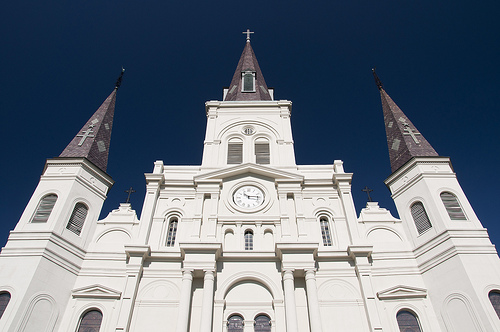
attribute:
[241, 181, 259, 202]
hands — black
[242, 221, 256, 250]
window — small, arched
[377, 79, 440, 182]
steeple — thatched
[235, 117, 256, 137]
vent — round, barred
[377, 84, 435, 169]
steeple — pointed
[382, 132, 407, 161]
diamond shape — grey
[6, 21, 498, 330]
church — stone, light colored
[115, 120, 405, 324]
building — white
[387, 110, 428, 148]
cross — light gray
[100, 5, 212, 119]
sky — blue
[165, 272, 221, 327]
pillar — white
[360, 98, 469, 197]
steeple — brownish red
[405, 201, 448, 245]
window — boarded up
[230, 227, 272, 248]
window case — arched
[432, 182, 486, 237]
window — closed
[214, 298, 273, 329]
arch — double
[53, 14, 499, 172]
sky — cloudless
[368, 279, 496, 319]
accent — triangular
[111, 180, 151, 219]
cross — metal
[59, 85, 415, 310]
church — large, white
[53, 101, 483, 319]
church — white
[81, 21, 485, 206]
spires — brown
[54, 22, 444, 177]
spires — three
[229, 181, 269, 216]
face — clock, white